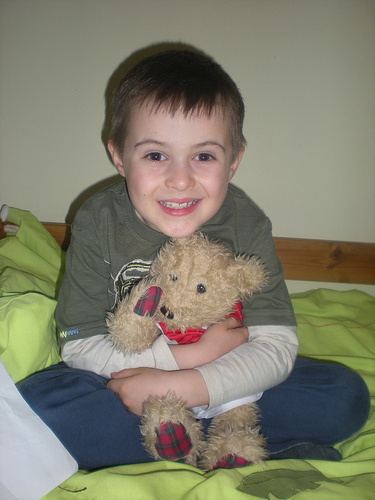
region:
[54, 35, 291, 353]
A young boy holding onto a teddy bear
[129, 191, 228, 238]
a wide smile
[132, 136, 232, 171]
a pair of eyes and eyebrows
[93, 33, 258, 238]
a youngs boy smiling at the camera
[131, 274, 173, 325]
the plaid paw of the teddy bear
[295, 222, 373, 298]
A wooden frame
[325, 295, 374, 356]
lime green sheets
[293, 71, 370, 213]
an ivory colored wall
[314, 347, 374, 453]
the knee of a person wearing jeans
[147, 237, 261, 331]
The face of a teddy bear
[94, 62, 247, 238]
child's smiling head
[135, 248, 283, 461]
child carrying a stuffed animal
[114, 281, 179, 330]
stuffed animal's paw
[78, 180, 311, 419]
child wearing a long sleeved shirt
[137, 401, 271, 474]
paws of the stuffed animal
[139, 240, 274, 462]
stuffed bear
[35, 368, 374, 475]
child wearing jeans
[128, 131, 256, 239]
child with a smile on his face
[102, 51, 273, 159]
close cut hair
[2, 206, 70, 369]
edge of the green blanket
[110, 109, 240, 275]
the boy is smiling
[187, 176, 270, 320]
the boy is smiling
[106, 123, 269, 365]
the boy is smiling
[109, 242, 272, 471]
a teddy bear in a boy's arms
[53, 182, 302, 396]
a gray and white shirt on a boy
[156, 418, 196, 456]
a red plaid foot on a teddy bear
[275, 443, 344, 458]
a dark gray sock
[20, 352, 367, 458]
blue pants on a boy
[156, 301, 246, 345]
a red ribbon on a shirt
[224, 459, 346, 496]
a green leaf pattern on a bedspread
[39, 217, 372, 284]
a wood headboard on a bed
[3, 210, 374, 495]
green sheets on a bed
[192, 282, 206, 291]
the eye of a stuffed bear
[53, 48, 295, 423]
boy holding teddy bear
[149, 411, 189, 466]
plaid paw of bear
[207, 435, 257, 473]
plaid paw of bear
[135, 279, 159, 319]
plaid paw of bear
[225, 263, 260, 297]
ear of teddy bear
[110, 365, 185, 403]
hand of little boy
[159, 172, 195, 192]
nose of little boy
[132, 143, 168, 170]
eye of little boy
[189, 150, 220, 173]
eye of little boy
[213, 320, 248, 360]
hand of little boy